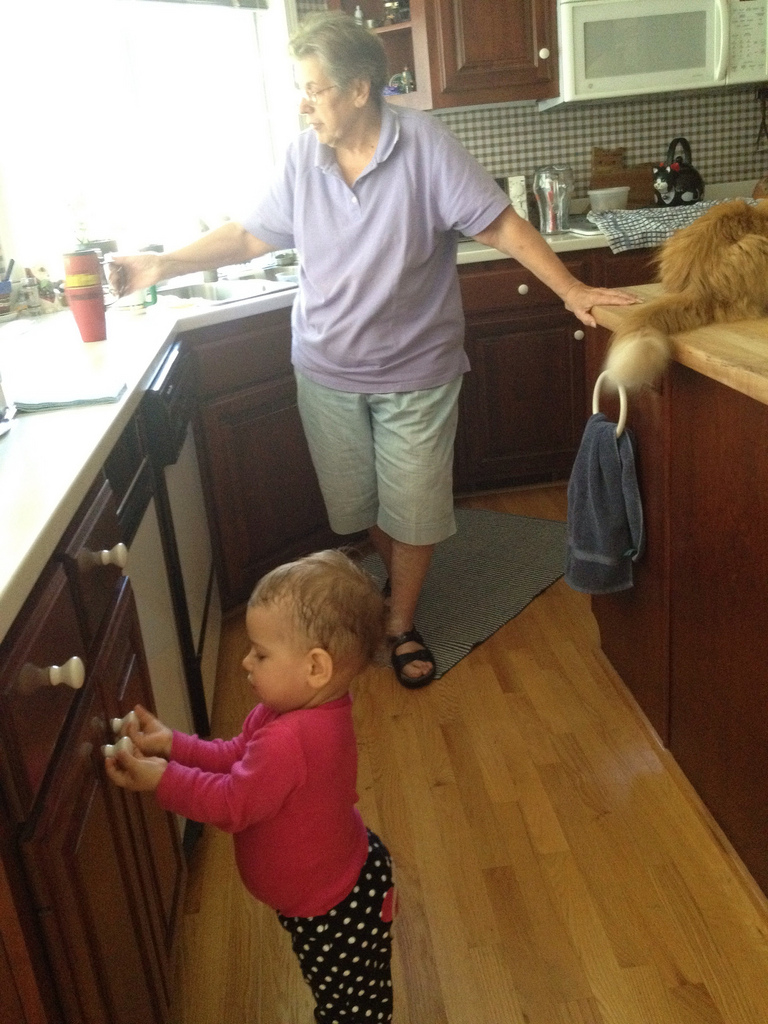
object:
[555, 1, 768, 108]
microwave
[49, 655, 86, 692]
knob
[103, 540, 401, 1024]
child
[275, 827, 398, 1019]
pants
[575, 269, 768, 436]
countertop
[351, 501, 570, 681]
rug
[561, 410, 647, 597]
towel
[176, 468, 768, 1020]
floor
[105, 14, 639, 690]
person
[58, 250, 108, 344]
coffee mug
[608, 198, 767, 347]
cat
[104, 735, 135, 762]
cabinet knob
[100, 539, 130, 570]
cabinet knob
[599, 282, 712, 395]
tail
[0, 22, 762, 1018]
kitchen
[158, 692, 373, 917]
shirt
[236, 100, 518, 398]
shirt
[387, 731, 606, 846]
ground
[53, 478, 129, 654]
drawer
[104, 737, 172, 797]
hand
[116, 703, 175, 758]
hand